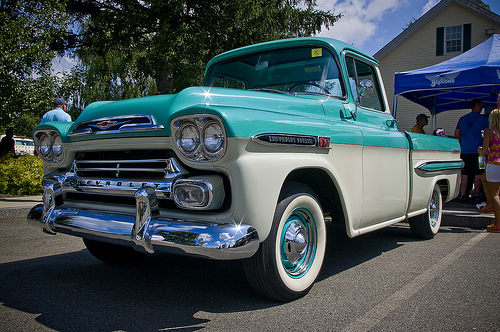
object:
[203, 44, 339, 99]
window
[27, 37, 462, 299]
car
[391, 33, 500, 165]
blue canopy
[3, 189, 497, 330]
driveway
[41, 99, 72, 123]
man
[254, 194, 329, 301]
tire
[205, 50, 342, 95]
windsheild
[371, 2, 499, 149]
building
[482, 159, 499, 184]
shorts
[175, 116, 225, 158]
headlight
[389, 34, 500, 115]
canopy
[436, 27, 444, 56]
shutter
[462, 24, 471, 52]
shutter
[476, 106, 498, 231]
woman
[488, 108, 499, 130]
hair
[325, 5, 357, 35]
cloud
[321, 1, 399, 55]
sky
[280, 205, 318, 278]
hubcap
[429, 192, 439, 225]
hubcap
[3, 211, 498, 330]
parking space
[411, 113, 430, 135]
man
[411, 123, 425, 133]
orange shirt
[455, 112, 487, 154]
shirt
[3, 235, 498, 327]
parking lot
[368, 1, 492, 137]
siding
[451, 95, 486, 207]
man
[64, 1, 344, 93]
tree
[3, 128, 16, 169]
person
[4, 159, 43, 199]
bush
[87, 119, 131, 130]
logo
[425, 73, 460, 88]
tarp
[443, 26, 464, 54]
bathroom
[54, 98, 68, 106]
cap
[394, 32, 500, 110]
roof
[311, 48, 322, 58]
sticker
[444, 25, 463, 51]
window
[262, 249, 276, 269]
part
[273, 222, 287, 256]
part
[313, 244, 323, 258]
part